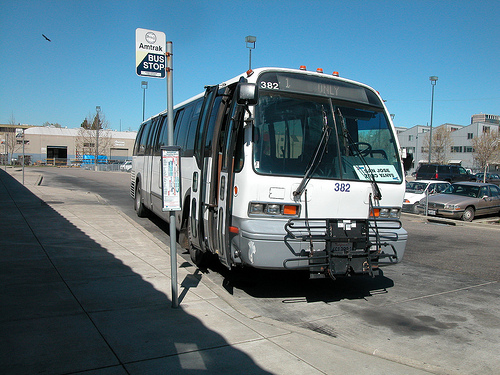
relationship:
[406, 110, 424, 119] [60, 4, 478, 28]
clouds are in sky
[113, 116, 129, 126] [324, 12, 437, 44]
clouds are in sky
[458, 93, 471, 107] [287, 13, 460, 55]
clouds are in sky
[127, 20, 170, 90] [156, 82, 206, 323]
sign attached to a post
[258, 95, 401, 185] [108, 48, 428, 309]
windshield of bus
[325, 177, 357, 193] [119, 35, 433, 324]
number on bus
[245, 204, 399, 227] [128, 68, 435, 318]
headlights on front of a bus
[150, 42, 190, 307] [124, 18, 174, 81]
pole holding up sign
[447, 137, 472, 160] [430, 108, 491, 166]
windows on a building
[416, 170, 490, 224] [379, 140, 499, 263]
car parked in a parking lot